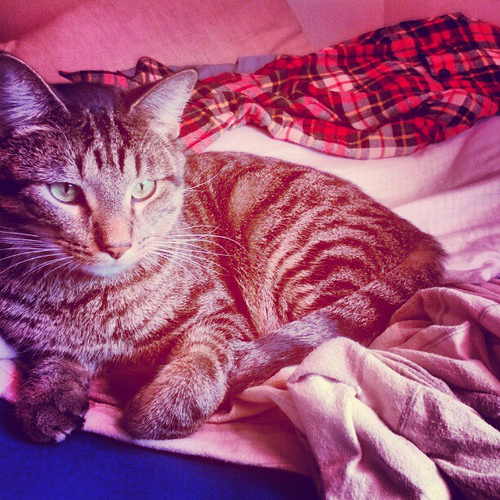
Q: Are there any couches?
A: Yes, there is a couch.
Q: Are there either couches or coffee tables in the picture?
A: Yes, there is a couch.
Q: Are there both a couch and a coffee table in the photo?
A: No, there is a couch but no coffee tables.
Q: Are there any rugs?
A: No, there are no rugs.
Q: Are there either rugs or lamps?
A: No, there are no rugs or lamps.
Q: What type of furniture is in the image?
A: The furniture is a couch.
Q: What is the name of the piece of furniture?
A: The piece of furniture is a couch.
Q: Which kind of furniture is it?
A: The piece of furniture is a couch.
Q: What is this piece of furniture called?
A: This is a couch.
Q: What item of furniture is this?
A: This is a couch.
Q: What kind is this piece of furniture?
A: This is a couch.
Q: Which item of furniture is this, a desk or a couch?
A: This is a couch.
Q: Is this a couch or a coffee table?
A: This is a couch.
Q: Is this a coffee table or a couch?
A: This is a couch.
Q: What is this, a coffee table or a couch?
A: This is a couch.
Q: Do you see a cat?
A: Yes, there is a cat.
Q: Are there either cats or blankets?
A: Yes, there is a cat.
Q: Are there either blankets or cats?
A: Yes, there is a cat.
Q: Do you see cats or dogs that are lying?
A: Yes, the cat is lying.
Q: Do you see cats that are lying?
A: Yes, there is a cat that is lying.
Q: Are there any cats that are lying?
A: Yes, there is a cat that is lying.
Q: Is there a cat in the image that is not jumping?
A: Yes, there is a cat that is lying.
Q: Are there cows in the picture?
A: No, there are no cows.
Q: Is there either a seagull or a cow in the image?
A: No, there are no cows or seagulls.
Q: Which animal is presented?
A: The animal is a cat.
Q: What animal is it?
A: The animal is a cat.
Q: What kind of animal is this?
A: This is a cat.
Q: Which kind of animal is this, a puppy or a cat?
A: This is a cat.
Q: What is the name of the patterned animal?
A: The animal is a cat.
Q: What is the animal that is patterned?
A: The animal is a cat.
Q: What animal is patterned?
A: The animal is a cat.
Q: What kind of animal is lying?
A: The animal is a cat.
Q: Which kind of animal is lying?
A: The animal is a cat.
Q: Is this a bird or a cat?
A: This is a cat.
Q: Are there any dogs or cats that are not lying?
A: No, there is a cat but it is lying.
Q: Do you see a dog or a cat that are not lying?
A: No, there is a cat but it is lying.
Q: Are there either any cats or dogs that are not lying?
A: No, there is a cat but it is lying.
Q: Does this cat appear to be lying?
A: Yes, the cat is lying.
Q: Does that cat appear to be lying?
A: Yes, the cat is lying.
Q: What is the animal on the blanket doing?
A: The cat is lying.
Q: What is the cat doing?
A: The cat is lying.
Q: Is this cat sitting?
A: No, the cat is lying.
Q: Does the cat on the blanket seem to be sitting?
A: No, the cat is lying.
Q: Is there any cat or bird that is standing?
A: No, there is a cat but it is lying.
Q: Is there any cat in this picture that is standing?
A: No, there is a cat but it is lying.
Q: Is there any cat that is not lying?
A: No, there is a cat but it is lying.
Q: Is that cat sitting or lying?
A: The cat is lying.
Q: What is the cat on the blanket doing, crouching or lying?
A: The cat is lying.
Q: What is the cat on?
A: The cat is on the blanket.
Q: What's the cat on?
A: The cat is on the blanket.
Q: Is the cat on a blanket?
A: Yes, the cat is on a blanket.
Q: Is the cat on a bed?
A: No, the cat is on a blanket.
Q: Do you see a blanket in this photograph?
A: Yes, there is a blanket.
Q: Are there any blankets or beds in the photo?
A: Yes, there is a blanket.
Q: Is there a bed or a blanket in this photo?
A: Yes, there is a blanket.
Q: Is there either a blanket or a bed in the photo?
A: Yes, there is a blanket.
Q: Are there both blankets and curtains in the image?
A: No, there is a blanket but no curtains.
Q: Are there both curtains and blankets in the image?
A: No, there is a blanket but no curtains.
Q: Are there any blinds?
A: No, there are no blinds.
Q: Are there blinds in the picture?
A: No, there are no blinds.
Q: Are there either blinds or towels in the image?
A: No, there are no blinds or towels.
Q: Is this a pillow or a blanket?
A: This is a blanket.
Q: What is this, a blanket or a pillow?
A: This is a blanket.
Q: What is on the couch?
A: The blanket is on the couch.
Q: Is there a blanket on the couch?
A: Yes, there is a blanket on the couch.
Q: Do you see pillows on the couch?
A: No, there is a blanket on the couch.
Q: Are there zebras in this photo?
A: No, there are no zebras.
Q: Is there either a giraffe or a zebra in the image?
A: No, there are no zebras or giraffes.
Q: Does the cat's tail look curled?
A: Yes, the tail is curled.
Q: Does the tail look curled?
A: Yes, the tail is curled.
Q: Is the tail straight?
A: No, the tail is curled.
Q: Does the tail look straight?
A: No, the tail is curled.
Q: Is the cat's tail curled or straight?
A: The tail is curled.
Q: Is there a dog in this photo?
A: No, there are no dogs.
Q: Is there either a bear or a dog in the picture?
A: No, there are no dogs or bears.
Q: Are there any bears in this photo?
A: No, there are no bears.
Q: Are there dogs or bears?
A: No, there are no bears or dogs.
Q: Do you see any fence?
A: No, there are no fences.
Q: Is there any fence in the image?
A: No, there are no fences.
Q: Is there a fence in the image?
A: No, there are no fences.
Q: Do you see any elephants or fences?
A: No, there are no fences or elephants.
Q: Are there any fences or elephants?
A: No, there are no fences or elephants.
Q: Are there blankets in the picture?
A: Yes, there is a blanket.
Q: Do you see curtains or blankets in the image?
A: Yes, there is a blanket.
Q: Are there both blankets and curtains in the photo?
A: No, there is a blanket but no curtains.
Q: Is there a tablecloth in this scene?
A: No, there are no tablecloths.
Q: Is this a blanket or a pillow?
A: This is a blanket.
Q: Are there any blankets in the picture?
A: Yes, there is a blanket.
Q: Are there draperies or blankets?
A: Yes, there is a blanket.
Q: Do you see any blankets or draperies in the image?
A: Yes, there is a blanket.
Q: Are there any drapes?
A: No, there are no drapes.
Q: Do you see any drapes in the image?
A: No, there are no drapes.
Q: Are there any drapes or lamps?
A: No, there are no drapes or lamps.